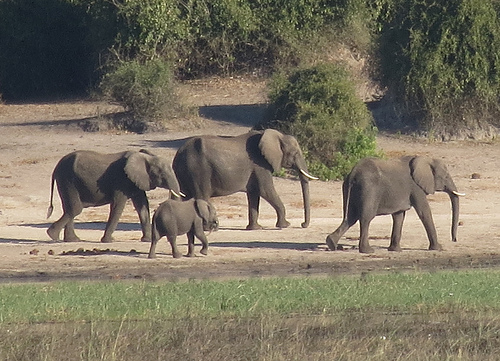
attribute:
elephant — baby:
[323, 146, 460, 256]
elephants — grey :
[36, 126, 464, 269]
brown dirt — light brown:
[3, 79, 498, 269]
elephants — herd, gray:
[28, 107, 470, 274]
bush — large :
[266, 56, 378, 188]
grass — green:
[4, 265, 499, 357]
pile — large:
[24, 246, 145, 259]